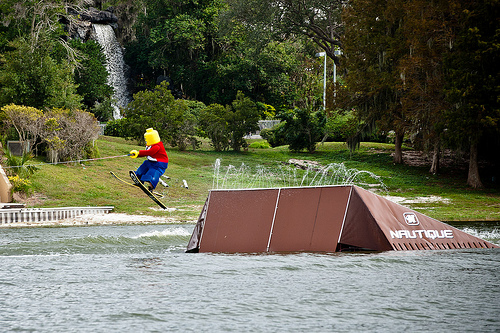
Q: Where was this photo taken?
A: Outside at the lake.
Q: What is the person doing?
A: Water skiing.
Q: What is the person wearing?
A: A costume.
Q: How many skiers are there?
A: 1.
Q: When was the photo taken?
A: During the day.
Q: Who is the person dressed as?
A: A lego man.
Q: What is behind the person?
A: A skiing jump.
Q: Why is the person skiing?
A: To have fun.